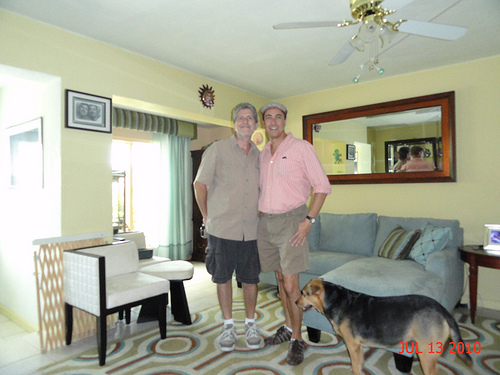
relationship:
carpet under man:
[193, 102, 265, 351] [28, 283, 497, 373]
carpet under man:
[193, 102, 265, 351] [246, 92, 328, 366]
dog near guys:
[294, 276, 471, 374] [188, 98, 271, 354]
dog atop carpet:
[294, 276, 471, 374] [167, 329, 337, 372]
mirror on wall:
[301, 90, 456, 185] [273, 54, 497, 313]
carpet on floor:
[29, 289, 497, 375] [194, 260, 215, 361]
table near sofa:
[447, 219, 498, 324] [275, 123, 465, 373]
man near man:
[246, 92, 328, 366] [189, 105, 276, 345]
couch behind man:
[266, 209, 470, 358] [252, 98, 334, 367]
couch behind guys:
[266, 209, 470, 358] [188, 98, 271, 354]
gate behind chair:
[0, 68, 61, 351] [56, 240, 173, 352]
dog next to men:
[296, 282, 473, 374] [191, 98, 323, 364]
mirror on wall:
[301, 106, 444, 175] [449, 67, 499, 189]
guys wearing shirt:
[188, 98, 271, 354] [182, 132, 272, 244]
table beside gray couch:
[453, 238, 500, 324] [295, 208, 464, 352]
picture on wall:
[63, 90, 113, 137] [2, 12, 268, 144]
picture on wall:
[63, 90, 113, 137] [283, 71, 495, 253]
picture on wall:
[63, 90, 113, 137] [42, 74, 124, 269]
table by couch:
[453, 238, 500, 324] [247, 208, 477, 330]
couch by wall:
[266, 209, 470, 358] [273, 54, 497, 313]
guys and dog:
[188, 98, 329, 368] [294, 276, 471, 374]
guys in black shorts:
[188, 98, 271, 354] [202, 229, 262, 285]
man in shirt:
[246, 92, 328, 366] [242, 131, 339, 215]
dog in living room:
[294, 276, 471, 374] [8, 14, 498, 337]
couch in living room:
[266, 209, 470, 358] [0, 1, 500, 372]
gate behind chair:
[29, 230, 116, 344] [60, 242, 170, 368]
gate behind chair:
[29, 230, 116, 344] [117, 227, 179, 332]